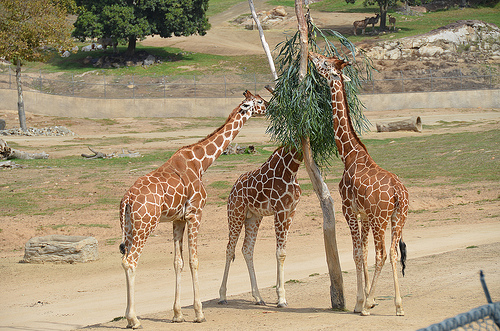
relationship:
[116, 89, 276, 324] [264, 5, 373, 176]
giraffes under limb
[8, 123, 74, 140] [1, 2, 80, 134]
rock around tree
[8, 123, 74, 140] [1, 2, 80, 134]
rock by tree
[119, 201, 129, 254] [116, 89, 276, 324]
tail on giraffes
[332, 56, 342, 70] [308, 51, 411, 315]
ear on giraffes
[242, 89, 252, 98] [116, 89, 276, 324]
horn on giraffes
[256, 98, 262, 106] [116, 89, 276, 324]
eye on giraffes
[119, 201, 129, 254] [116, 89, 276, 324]
tail of giraffes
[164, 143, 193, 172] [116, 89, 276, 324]
back of giraffes